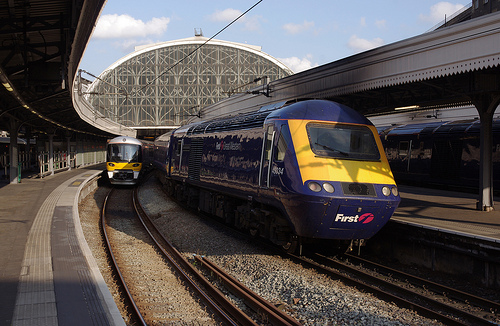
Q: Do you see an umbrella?
A: No, there are no umbrellas.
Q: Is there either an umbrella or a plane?
A: No, there are no umbrellas or airplanes.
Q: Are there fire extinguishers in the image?
A: No, there are no fire extinguishers.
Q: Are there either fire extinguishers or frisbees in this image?
A: No, there are no fire extinguishers or frisbees.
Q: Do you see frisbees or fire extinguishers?
A: No, there are no fire extinguishers or frisbees.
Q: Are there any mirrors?
A: No, there are no mirrors.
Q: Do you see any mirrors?
A: No, there are no mirrors.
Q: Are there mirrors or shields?
A: No, there are no mirrors or shields.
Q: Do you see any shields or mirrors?
A: No, there are no mirrors or shields.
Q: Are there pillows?
A: No, there are no pillows.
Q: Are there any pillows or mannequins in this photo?
A: No, there are no pillows or mannequins.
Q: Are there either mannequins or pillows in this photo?
A: No, there are no pillows or mannequins.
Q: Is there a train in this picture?
A: Yes, there is a train.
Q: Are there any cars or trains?
A: Yes, there is a train.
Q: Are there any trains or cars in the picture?
A: Yes, there is a train.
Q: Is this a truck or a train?
A: This is a train.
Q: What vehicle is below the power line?
A: The vehicle is a train.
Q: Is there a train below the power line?
A: Yes, there is a train below the power line.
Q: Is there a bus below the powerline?
A: No, there is a train below the powerline.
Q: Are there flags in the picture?
A: No, there are no flags.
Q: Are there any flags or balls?
A: No, there are no flags or balls.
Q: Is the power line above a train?
A: Yes, the power line is above a train.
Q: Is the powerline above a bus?
A: No, the powerline is above a train.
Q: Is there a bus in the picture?
A: No, there are no buses.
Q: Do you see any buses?
A: No, there are no buses.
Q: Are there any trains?
A: Yes, there is a train.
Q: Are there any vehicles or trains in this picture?
A: Yes, there is a train.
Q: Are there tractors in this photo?
A: No, there are no tractors.